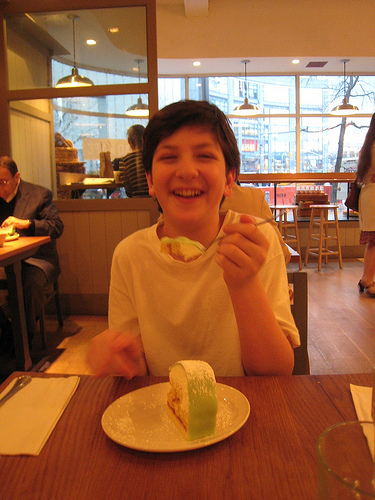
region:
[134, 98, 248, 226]
child smiling at camera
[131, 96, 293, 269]
child holding up spoon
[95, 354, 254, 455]
dessert with powdered sugar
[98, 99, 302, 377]
child wearing white t-shirt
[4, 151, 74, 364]
man sitting at restaurant table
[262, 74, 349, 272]
wooden stools by window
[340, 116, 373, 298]
woman with brown purse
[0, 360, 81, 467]
paper napkin on table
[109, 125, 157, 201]
person in striped shirt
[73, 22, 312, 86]
recessed lighting on ceiling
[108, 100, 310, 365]
A child sitting at a table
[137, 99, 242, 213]
A child with a big smile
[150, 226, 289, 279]
A fork in childs hand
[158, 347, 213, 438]
A large slice of cake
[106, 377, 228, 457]
A white plate with a slice of cake on it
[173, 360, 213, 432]
A slice of cake with green icing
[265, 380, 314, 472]
A brown wooden table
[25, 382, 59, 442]
A white napkin on a table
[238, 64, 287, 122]
A metal hanging light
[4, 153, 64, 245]
A man in a suit sitting at a table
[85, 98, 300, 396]
boy holding spoon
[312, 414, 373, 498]
glass sitting on table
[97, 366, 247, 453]
white plate on wood table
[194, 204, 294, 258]
spoon boy is holding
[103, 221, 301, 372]
white shirt of boy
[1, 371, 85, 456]
white napkin on corner of table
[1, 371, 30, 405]
silver handle of utensil on napkin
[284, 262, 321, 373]
chair boy is sitting on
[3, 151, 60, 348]
man with glasses sitting at other table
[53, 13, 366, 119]
drop lights hanging from ceiling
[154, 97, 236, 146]
Person has brown hair.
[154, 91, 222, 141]
Person has short hair.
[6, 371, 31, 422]
Silver utensil on top of napkin.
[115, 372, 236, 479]
Food on top of white plate.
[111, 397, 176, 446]
Powdered sugar on plate.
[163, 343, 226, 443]
Food has green top coat.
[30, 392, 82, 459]
White napkin on table.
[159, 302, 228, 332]
Person wearing white shirt.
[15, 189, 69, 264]
Person wearing dark suit.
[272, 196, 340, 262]
Wooden stools near window.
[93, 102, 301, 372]
A smiling young boy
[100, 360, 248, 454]
A slice of cake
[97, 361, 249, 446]
A slice of cake on a white plate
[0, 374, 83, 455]
A white napkin on a table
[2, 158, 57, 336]
An elderly man sitting at a table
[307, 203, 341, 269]
A small bar stool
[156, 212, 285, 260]
A fork with a slice of cake on it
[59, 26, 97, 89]
A light hanging from the ceiling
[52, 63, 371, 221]
A large bay window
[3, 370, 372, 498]
A wooden table